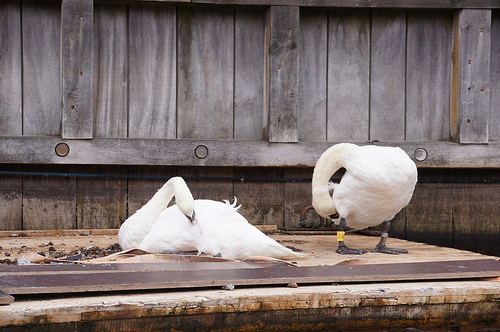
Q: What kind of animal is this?
A: Bird.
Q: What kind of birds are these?
A: Swans.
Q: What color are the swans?
A: White.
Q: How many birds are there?
A: Two.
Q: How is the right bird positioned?
A: Standing.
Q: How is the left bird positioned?
A: Lying down.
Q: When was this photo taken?
A: During the day.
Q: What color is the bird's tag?
A: Yellow.